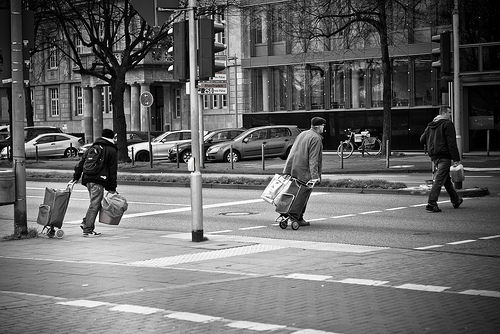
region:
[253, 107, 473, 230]
the people crossing the street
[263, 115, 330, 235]
the man dragging his bags across the street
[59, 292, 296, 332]
the white dashes in the road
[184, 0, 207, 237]
the post for the traffic signal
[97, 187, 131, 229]
the bag in the hand of the man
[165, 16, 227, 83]
tyhe traffic lights on the pole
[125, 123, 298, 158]
the cars parked in the lot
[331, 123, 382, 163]
the bike agianst the building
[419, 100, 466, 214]
the man carrying the container across the street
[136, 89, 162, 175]
the sign on the side of the road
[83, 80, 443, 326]
shade is black and white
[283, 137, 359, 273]
a man is crossing the treet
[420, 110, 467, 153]
jacket is black in color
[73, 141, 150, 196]
mn carying a bag at his back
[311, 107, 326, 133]
cape is black in color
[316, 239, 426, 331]
road has white lanes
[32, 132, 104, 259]
man is rolling a briefcase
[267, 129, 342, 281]
man is in the middle of crossway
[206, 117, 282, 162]
cars are parked at the roadside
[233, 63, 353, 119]
the cars re next to the building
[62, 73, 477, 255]
people crossing the street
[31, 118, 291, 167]
the cars are parked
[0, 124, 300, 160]
The vehicles are parked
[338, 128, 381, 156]
A bicycle near the tree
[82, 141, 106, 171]
The person is wearing a backpack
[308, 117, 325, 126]
The man is wearing a hat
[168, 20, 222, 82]
Traffic lights above the street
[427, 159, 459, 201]
The man is wearing pants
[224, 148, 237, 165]
The front wheel of the car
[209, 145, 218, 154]
A headlight on the car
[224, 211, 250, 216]
A manhole cover on the street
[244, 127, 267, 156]
The driver's door of the car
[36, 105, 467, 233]
Three people walking across a street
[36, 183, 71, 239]
Luggage with wheels behind a person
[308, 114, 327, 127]
A cap on a man's head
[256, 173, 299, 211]
A large paper sack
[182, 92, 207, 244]
A metal sign pole on a street corner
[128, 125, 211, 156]
A parked car on the side of the street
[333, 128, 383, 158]
A bicyle parked at a curb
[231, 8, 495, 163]
A large building on a downtown street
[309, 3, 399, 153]
A tall barren tree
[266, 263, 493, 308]
Dashed line painted on a street